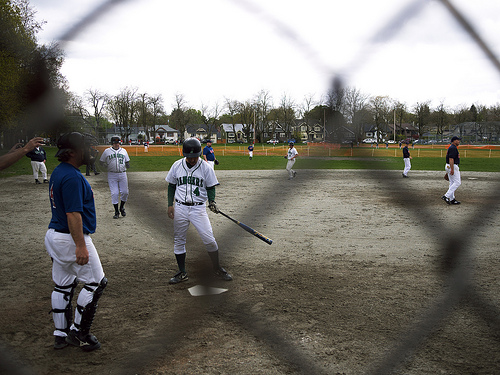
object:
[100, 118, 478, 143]
houses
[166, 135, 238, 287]
man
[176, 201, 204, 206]
belt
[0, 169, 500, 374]
dirt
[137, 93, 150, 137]
tree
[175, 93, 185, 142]
tree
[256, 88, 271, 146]
tree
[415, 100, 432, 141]
tree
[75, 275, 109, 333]
guard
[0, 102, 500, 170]
distance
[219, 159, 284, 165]
green grass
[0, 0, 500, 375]
chain link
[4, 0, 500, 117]
sky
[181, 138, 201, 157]
helmet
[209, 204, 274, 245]
baseball bat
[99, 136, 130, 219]
runner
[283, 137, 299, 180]
runner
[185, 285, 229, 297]
base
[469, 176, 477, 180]
base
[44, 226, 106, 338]
pants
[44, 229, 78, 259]
butt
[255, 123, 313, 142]
houses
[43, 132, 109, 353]
catcher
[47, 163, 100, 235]
blue shirt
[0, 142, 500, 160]
fence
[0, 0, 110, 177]
tree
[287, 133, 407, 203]
outfield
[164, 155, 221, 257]
jersey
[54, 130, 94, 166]
equipment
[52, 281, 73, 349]
equipment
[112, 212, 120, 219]
base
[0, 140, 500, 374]
baseball field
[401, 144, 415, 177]
player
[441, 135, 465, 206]
player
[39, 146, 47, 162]
arm